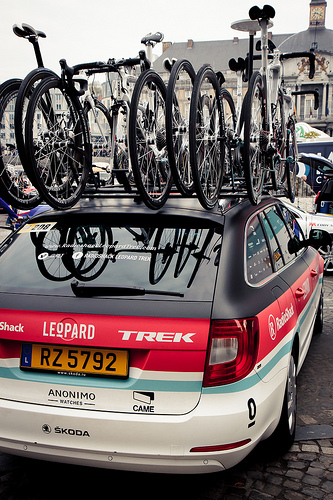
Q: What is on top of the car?
A: Bicycles.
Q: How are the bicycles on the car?
A: Rack.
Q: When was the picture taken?
A: Daytime.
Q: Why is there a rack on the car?
A: To hold the bicycles.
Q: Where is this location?
A: Parking lot.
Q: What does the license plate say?
A: RZ 5792.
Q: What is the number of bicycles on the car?
A: Five.